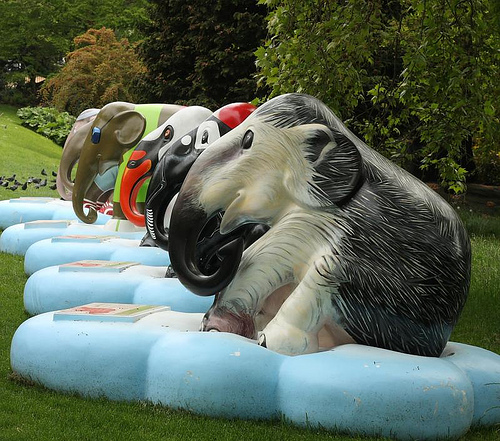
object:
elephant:
[71, 98, 189, 224]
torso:
[122, 101, 162, 188]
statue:
[9, 92, 497, 436]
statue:
[23, 103, 213, 276]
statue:
[0, 100, 186, 257]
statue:
[54, 107, 100, 231]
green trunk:
[72, 145, 96, 225]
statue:
[64, 96, 183, 226]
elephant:
[166, 92, 471, 357]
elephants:
[56, 92, 473, 357]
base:
[7, 305, 496, 437]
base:
[23, 260, 214, 316]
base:
[23, 230, 172, 275]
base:
[0, 220, 144, 255]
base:
[0, 195, 83, 228]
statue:
[145, 101, 260, 248]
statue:
[119, 106, 214, 223]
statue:
[70, 97, 202, 223]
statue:
[50, 102, 101, 196]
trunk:
[174, 198, 244, 295]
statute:
[56, 122, 109, 211]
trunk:
[167, 187, 244, 299]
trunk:
[143, 158, 193, 249]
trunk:
[118, 151, 165, 227]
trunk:
[69, 171, 96, 223]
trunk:
[54, 149, 79, 199]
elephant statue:
[144, 102, 258, 252]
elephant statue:
[119, 104, 216, 226]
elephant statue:
[53, 106, 100, 201]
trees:
[11, 4, 491, 109]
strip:
[89, 125, 106, 143]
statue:
[73, 97, 180, 227]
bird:
[20, 180, 28, 190]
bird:
[49, 171, 58, 178]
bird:
[39, 165, 47, 176]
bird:
[5, 178, 19, 191]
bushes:
[16, 101, 75, 146]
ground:
[4, 389, 154, 439]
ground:
[479, 184, 497, 346]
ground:
[0, 249, 21, 312]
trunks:
[131, 194, 353, 343]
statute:
[144, 103, 254, 246]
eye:
[239, 126, 254, 150]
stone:
[6, 302, 499, 439]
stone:
[24, 258, 222, 312]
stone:
[24, 232, 175, 274]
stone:
[0, 217, 175, 259]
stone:
[0, 194, 103, 234]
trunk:
[94, 67, 473, 372]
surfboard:
[13, 407, 151, 434]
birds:
[0, 166, 63, 194]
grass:
[0, 132, 47, 167]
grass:
[0, 123, 25, 154]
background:
[2, 0, 484, 98]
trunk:
[119, 142, 150, 223]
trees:
[2, 2, 496, 189]